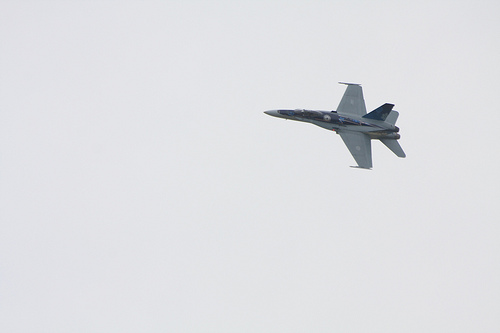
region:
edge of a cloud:
[227, 182, 240, 187]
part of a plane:
[360, 155, 365, 184]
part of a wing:
[358, 150, 372, 165]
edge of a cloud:
[235, 199, 243, 213]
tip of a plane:
[264, 109, 274, 122]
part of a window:
[331, 111, 337, 118]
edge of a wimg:
[346, 148, 376, 180]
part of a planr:
[350, 103, 381, 128]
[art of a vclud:
[211, 205, 242, 240]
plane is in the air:
[276, 72, 432, 214]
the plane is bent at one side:
[244, 54, 429, 175]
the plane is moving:
[251, 83, 425, 168]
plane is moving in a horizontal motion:
[251, 51, 407, 173]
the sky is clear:
[227, 29, 451, 227]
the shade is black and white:
[255, 49, 437, 206]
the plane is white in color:
[254, 79, 431, 179]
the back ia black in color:
[279, 94, 346, 126]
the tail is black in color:
[355, 95, 405, 115]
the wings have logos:
[343, 81, 375, 168]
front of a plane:
[260, 85, 318, 133]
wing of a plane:
[329, 67, 371, 118]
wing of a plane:
[338, 140, 385, 176]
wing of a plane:
[359, 85, 403, 126]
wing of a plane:
[375, 132, 417, 164]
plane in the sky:
[242, 60, 425, 177]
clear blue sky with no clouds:
[83, 207, 302, 278]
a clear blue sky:
[54, 160, 161, 279]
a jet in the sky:
[229, 54, 454, 186]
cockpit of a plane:
[276, 95, 328, 132]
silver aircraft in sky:
[259, 62, 428, 193]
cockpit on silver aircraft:
[272, 104, 313, 124]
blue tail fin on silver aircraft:
[362, 102, 399, 122]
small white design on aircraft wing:
[347, 138, 367, 156]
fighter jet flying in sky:
[230, 73, 422, 191]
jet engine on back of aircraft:
[376, 119, 411, 144]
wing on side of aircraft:
[325, 70, 371, 115]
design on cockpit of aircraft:
[322, 110, 333, 124]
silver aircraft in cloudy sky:
[236, 55, 435, 190]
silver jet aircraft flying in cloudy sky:
[247, 73, 425, 182]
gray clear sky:
[0, 6, 496, 331]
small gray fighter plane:
[257, 72, 418, 184]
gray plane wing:
[330, 75, 369, 114]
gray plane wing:
[337, 125, 377, 171]